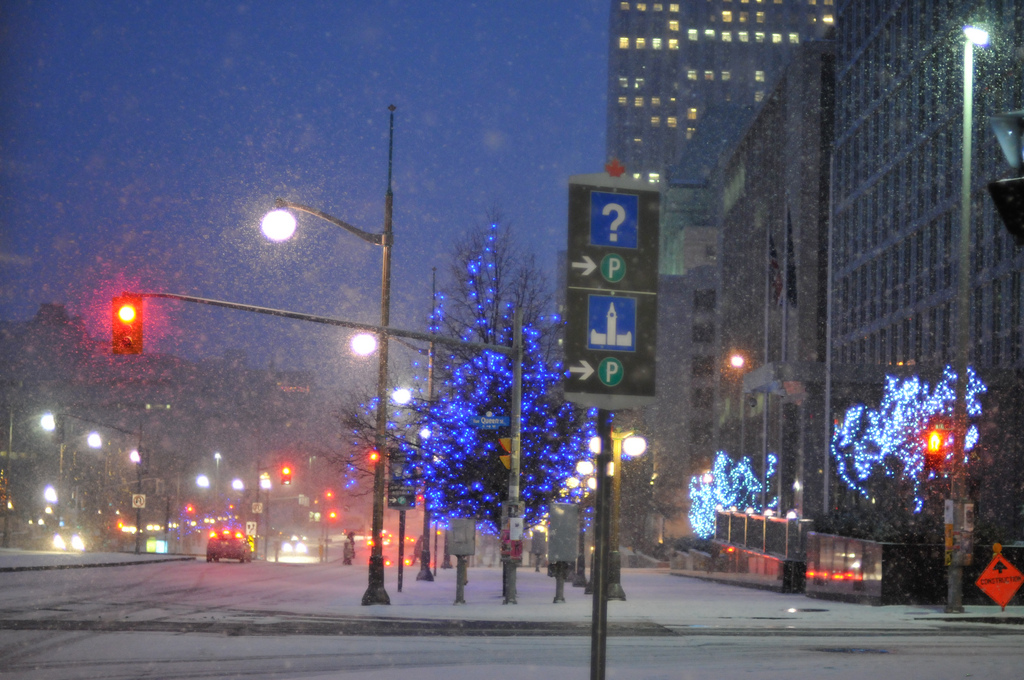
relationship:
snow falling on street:
[12, 11, 513, 675] [23, 552, 916, 656]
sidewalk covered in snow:
[239, 539, 471, 610] [324, 601, 435, 612]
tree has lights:
[431, 243, 570, 557] [423, 294, 598, 542]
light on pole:
[910, 411, 961, 472] [958, 109, 974, 611]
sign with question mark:
[577, 195, 645, 249] [595, 200, 628, 246]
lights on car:
[207, 521, 246, 544] [204, 522, 254, 561]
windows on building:
[621, 8, 808, 47] [627, 33, 749, 172]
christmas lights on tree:
[384, 218, 597, 522] [384, 218, 597, 599]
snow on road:
[5, 546, 1023, 677] [5, 546, 1023, 677]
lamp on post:
[960, 18, 998, 51] [936, 51, 988, 614]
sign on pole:
[473, 404, 506, 434] [501, 307, 527, 586]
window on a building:
[666, 32, 683, 55] [598, 0, 836, 210]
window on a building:
[662, 5, 678, 41] [609, 2, 837, 281]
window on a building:
[682, 19, 698, 45] [603, 0, 847, 166]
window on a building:
[750, 29, 769, 49] [614, 0, 856, 179]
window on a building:
[718, 28, 735, 48] [609, 0, 865, 193]